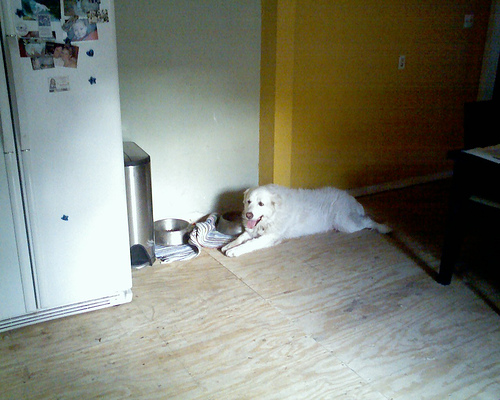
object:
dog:
[221, 182, 392, 257]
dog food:
[162, 227, 181, 233]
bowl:
[153, 218, 191, 244]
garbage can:
[123, 141, 156, 270]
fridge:
[0, 0, 135, 333]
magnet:
[87, 76, 96, 85]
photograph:
[42, 41, 80, 69]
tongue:
[244, 219, 255, 228]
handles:
[0, 123, 17, 205]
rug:
[154, 212, 237, 263]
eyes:
[257, 201, 264, 206]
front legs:
[224, 235, 273, 258]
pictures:
[45, 77, 70, 94]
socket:
[399, 57, 406, 69]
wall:
[113, 0, 264, 235]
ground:
[0, 229, 500, 400]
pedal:
[130, 243, 153, 269]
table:
[437, 145, 500, 288]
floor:
[0, 222, 500, 400]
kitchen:
[0, 0, 500, 400]